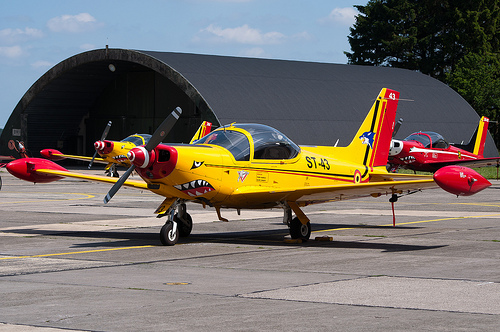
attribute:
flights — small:
[3, 86, 492, 242]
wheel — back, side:
[287, 210, 312, 244]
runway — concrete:
[2, 164, 482, 330]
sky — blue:
[1, 0, 372, 130]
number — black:
[320, 159, 331, 174]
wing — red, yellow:
[230, 160, 485, 210]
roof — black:
[128, 48, 493, 148]